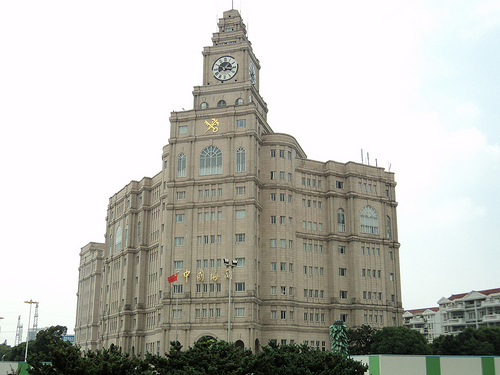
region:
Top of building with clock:
[185, 0, 260, 80]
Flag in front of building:
[155, 265, 185, 290]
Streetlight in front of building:
[215, 250, 240, 335]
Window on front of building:
[190, 140, 225, 180]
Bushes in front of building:
[170, 330, 255, 370]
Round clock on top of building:
[210, 50, 235, 75]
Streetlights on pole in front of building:
[215, 250, 235, 270]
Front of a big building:
[160, 0, 265, 335]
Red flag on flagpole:
[160, 263, 181, 338]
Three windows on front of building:
[170, 142, 249, 179]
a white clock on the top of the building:
[210, 55, 235, 78]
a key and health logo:
[201, 115, 216, 130]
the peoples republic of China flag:
[165, 270, 175, 281]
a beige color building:
[71, 0, 401, 366]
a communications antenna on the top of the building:
[228, 0, 234, 11]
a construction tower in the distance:
[25, 298, 39, 336]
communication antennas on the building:
[359, 145, 393, 171]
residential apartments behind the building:
[404, 288, 499, 336]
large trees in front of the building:
[31, 340, 368, 374]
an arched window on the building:
[198, 146, 225, 176]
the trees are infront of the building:
[46, 330, 342, 374]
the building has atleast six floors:
[111, 121, 405, 340]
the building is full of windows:
[75, 131, 410, 327]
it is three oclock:
[204, 55, 241, 81]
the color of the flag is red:
[162, 259, 183, 286]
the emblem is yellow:
[191, 118, 230, 135]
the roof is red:
[415, 304, 440, 311]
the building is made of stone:
[68, 111, 399, 333]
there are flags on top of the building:
[342, 148, 399, 168]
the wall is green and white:
[371, 351, 486, 374]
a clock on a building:
[190, 2, 262, 123]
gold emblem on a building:
[200, 112, 227, 139]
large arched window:
[193, 140, 230, 182]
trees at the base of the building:
[1, 333, 373, 373]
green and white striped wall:
[331, 347, 498, 373]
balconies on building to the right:
[399, 282, 498, 336]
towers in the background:
[0, 299, 50, 369]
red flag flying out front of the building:
[165, 267, 186, 347]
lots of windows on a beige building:
[260, 186, 327, 301]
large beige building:
[39, 2, 454, 362]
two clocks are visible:
[186, 11, 272, 98]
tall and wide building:
[55, 5, 425, 364]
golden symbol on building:
[181, 101, 243, 143]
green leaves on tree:
[9, 321, 363, 371]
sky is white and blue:
[3, 0, 492, 291]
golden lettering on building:
[168, 263, 250, 290]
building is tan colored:
[67, 11, 420, 359]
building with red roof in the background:
[392, 283, 497, 347]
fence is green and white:
[334, 346, 495, 373]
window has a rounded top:
[192, 141, 234, 178]